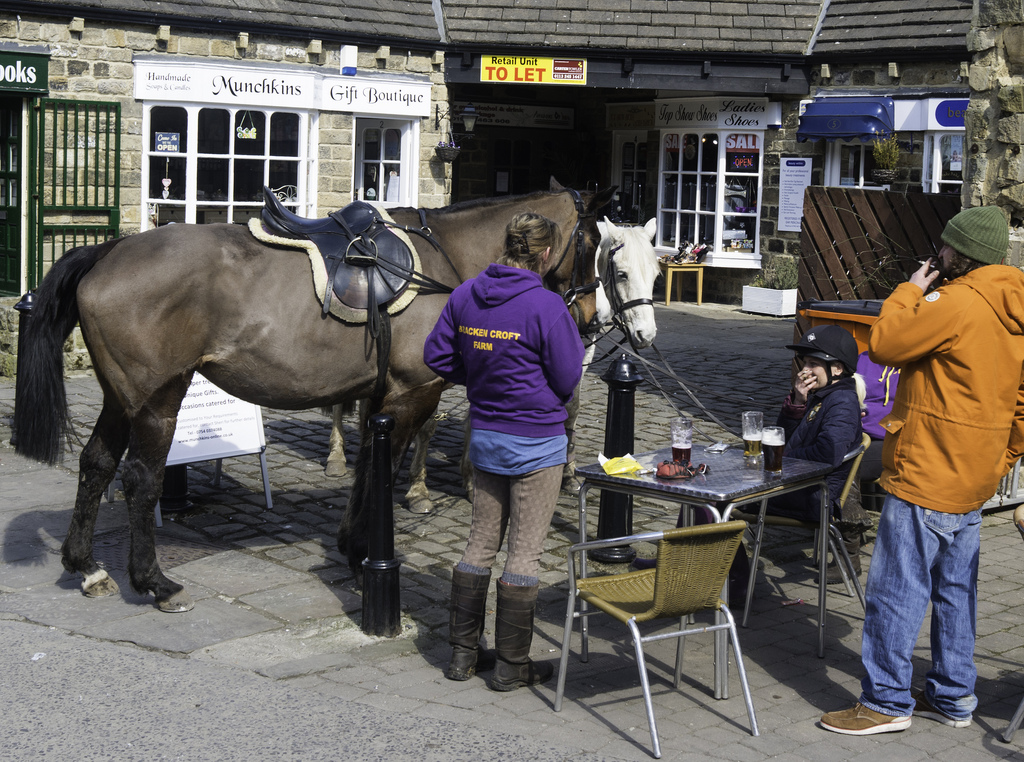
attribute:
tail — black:
[19, 220, 102, 454]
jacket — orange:
[855, 267, 1022, 520]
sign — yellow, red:
[476, 55, 587, 88]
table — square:
[564, 426, 845, 504]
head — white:
[584, 217, 695, 388]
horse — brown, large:
[9, 173, 601, 619]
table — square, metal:
[545, 434, 854, 668]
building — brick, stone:
[13, 6, 1022, 393]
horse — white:
[594, 214, 675, 362]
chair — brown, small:
[555, 512, 759, 759]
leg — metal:
[717, 594, 761, 739]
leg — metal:
[624, 615, 670, 760]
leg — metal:
[548, 574, 572, 717]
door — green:
[1, 91, 38, 301]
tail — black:
[14, 238, 108, 463]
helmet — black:
[782, 322, 862, 375]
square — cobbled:
[4, 302, 1022, 760]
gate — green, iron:
[1, 93, 36, 297]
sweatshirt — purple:
[419, 250, 584, 436]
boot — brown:
[442, 557, 497, 685]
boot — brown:
[488, 574, 558, 689]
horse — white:
[326, 212, 666, 519]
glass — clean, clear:
[386, 127, 404, 167]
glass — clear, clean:
[360, 166, 380, 201]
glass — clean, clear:
[358, 166, 378, 203]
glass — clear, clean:
[267, 155, 296, 201]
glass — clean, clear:
[237, 155, 270, 203]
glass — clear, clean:
[190, 158, 232, 202]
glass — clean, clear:
[140, 157, 190, 203]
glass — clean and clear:
[194, 104, 231, 156]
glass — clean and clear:
[233, 106, 270, 156]